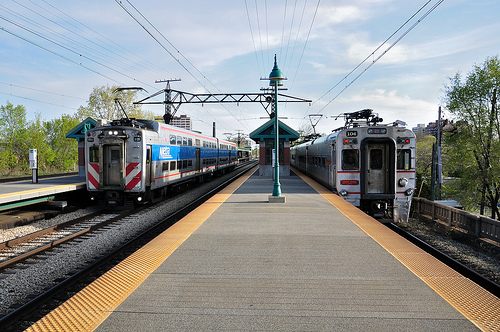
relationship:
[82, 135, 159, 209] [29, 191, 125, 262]
train on tracks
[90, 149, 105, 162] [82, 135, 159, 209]
window of train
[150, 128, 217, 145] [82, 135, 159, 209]
windows on train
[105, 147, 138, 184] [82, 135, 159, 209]
door of train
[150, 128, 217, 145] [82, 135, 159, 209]
windows of train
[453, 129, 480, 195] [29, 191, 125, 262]
bushes by tracks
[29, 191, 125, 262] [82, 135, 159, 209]
tracks under train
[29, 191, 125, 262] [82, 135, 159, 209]
tracks by train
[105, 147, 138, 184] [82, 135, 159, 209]
door on train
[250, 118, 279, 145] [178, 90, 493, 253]
covering at station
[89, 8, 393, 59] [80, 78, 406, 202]
wires for trains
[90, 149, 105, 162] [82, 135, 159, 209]
window on train